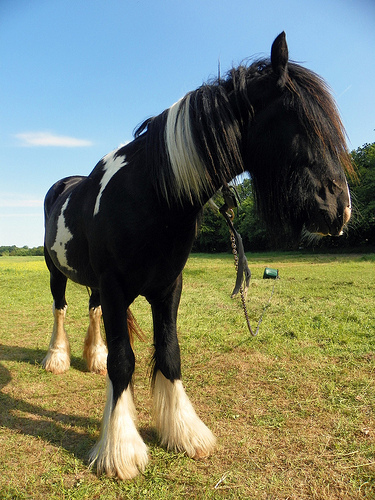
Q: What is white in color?
A: The feet on the horse.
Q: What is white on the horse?
A: Fur.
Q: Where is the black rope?
A: On horse.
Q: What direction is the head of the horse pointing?
A: The right.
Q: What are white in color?
A: The hooves.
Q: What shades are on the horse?
A: Black and white.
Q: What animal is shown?
A: Horse.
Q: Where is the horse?
A: IN a pasture.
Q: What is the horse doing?
A: Standing.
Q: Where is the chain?
A: Around the horse.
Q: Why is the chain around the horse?
A: To keep it there.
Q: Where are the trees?
A: Behind the horse.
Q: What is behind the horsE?
A: Trees.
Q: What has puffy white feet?
A: The pony.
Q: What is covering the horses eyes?
A: Hair.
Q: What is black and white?
A: The horse.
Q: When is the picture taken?
A: Daytime.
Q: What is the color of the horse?
A: Black and white.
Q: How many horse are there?
A: One.